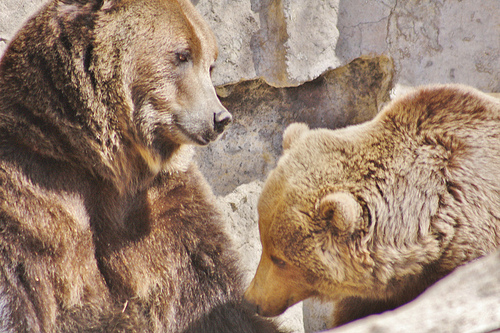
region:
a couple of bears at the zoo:
[9, 3, 499, 320]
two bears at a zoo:
[11, 11, 480, 316]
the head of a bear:
[228, 110, 367, 328]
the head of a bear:
[27, 0, 245, 159]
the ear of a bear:
[315, 188, 358, 235]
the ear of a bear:
[274, 115, 314, 155]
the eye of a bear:
[265, 250, 290, 272]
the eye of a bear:
[168, 43, 193, 67]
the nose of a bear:
[234, 261, 271, 327]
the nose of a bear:
[201, 100, 240, 138]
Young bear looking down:
[241, 77, 499, 325]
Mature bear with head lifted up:
[1, 0, 241, 331]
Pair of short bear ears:
[274, 116, 366, 238]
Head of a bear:
[60, 0, 236, 150]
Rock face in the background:
[189, 0, 499, 332]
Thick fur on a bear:
[0, 25, 272, 332]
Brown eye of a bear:
[174, 45, 190, 65]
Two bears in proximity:
[0, 0, 497, 330]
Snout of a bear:
[153, 65, 238, 147]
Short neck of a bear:
[350, 106, 426, 304]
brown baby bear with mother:
[237, 80, 498, 327]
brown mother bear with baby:
[1, 6, 291, 327]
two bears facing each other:
[3, 0, 497, 330]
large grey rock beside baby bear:
[322, 246, 498, 327]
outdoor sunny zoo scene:
[5, 0, 496, 323]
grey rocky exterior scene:
[15, 8, 496, 327]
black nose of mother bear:
[171, 95, 236, 151]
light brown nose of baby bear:
[235, 266, 296, 317]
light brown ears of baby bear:
[280, 118, 358, 231]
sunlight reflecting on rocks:
[210, 1, 499, 201]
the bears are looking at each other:
[80, 59, 425, 306]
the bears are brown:
[80, 107, 422, 268]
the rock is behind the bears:
[225, 17, 470, 212]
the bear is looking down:
[217, 128, 360, 303]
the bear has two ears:
[261, 120, 396, 317]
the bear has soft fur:
[358, 102, 490, 237]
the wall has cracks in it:
[364, 5, 461, 55]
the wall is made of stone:
[221, 28, 416, 190]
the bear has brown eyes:
[147, 39, 231, 79]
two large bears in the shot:
[1, 2, 498, 331]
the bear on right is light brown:
[247, 85, 497, 327]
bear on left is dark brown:
[1, 0, 293, 331]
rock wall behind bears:
[1, 0, 498, 332]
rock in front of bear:
[307, 245, 499, 331]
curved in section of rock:
[191, 56, 395, 331]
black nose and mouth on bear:
[172, 105, 234, 148]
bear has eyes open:
[174, 48, 214, 77]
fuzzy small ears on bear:
[281, 118, 356, 228]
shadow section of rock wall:
[194, 56, 389, 330]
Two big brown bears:
[8, 3, 498, 331]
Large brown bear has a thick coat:
[3, 26, 262, 331]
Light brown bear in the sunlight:
[246, 80, 499, 316]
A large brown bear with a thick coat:
[3, 3, 240, 328]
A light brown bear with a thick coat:
[237, 78, 493, 319]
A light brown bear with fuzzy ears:
[246, 83, 498, 320]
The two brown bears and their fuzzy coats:
[23, 6, 473, 317]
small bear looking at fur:
[234, 69, 499, 321]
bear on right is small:
[240, 69, 498, 319]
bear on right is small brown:
[234, 76, 499, 326]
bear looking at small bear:
[2, 2, 292, 332]